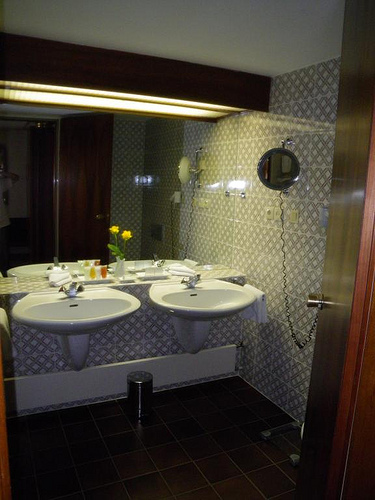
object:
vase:
[112, 253, 127, 283]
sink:
[9, 284, 140, 373]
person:
[0, 158, 21, 267]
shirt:
[0, 178, 14, 228]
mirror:
[253, 148, 301, 191]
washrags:
[46, 269, 72, 287]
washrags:
[168, 263, 196, 277]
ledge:
[0, 263, 243, 296]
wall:
[0, 58, 338, 426]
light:
[2, 80, 253, 123]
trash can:
[127, 370, 153, 417]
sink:
[144, 264, 273, 356]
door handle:
[305, 294, 336, 309]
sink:
[105, 233, 200, 281]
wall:
[4, 60, 275, 411]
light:
[201, 167, 248, 216]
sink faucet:
[165, 248, 217, 299]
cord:
[272, 193, 315, 352]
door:
[298, 5, 374, 495]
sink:
[0, 245, 105, 282]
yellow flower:
[103, 223, 163, 277]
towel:
[242, 276, 278, 342]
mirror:
[1, 94, 240, 289]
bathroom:
[4, 7, 374, 499]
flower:
[107, 225, 121, 236]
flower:
[118, 228, 137, 258]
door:
[303, 106, 363, 438]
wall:
[238, 213, 275, 262]